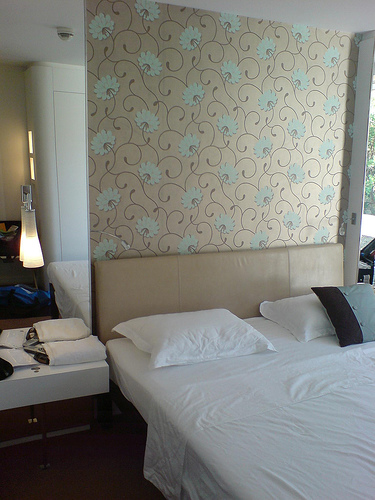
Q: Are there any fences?
A: No, there are no fences.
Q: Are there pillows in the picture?
A: Yes, there is a pillow.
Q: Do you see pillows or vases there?
A: Yes, there is a pillow.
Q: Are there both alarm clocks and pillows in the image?
A: No, there is a pillow but no alarm clocks.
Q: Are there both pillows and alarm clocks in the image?
A: No, there is a pillow but no alarm clocks.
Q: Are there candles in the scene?
A: No, there are no candles.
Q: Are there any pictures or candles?
A: No, there are no candles or pictures.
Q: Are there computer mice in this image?
A: No, there are no computer mice.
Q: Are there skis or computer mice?
A: No, there are no computer mice or skis.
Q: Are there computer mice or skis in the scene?
A: No, there are no computer mice or skis.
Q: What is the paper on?
A: The paper is on the counter.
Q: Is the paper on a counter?
A: Yes, the paper is on a counter.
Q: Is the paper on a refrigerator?
A: No, the paper is on a counter.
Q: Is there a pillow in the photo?
A: Yes, there are pillows.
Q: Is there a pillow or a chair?
A: Yes, there are pillows.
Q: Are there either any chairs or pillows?
A: Yes, there are pillows.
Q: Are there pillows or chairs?
A: Yes, there are pillows.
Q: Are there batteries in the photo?
A: No, there are no batteries.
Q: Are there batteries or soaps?
A: No, there are no batteries or soaps.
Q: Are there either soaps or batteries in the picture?
A: No, there are no batteries or soaps.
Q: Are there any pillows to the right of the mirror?
A: Yes, there are pillows to the right of the mirror.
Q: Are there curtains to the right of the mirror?
A: No, there are pillows to the right of the mirror.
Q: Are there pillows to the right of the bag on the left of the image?
A: Yes, there are pillows to the right of the bag.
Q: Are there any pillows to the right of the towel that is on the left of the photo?
A: Yes, there are pillows to the right of the towel.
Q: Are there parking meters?
A: No, there are no parking meters.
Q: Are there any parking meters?
A: No, there are no parking meters.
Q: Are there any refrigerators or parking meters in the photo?
A: No, there are no parking meters or refrigerators.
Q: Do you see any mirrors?
A: Yes, there is a mirror.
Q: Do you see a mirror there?
A: Yes, there is a mirror.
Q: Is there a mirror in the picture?
A: Yes, there is a mirror.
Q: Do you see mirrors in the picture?
A: Yes, there is a mirror.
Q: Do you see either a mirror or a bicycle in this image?
A: Yes, there is a mirror.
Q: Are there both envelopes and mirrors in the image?
A: No, there is a mirror but no envelopes.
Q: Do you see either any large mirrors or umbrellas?
A: Yes, there is a large mirror.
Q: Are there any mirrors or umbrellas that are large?
A: Yes, the mirror is large.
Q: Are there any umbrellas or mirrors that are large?
A: Yes, the mirror is large.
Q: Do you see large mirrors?
A: Yes, there is a large mirror.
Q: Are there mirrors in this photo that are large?
A: Yes, there is a mirror that is large.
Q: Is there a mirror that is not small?
A: Yes, there is a large mirror.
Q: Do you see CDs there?
A: No, there are no cds.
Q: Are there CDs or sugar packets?
A: No, there are no CDs or sugar packets.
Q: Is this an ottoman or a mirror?
A: This is a mirror.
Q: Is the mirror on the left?
A: Yes, the mirror is on the left of the image.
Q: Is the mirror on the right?
A: No, the mirror is on the left of the image.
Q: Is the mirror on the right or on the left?
A: The mirror is on the left of the image.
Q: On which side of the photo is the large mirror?
A: The mirror is on the left of the image.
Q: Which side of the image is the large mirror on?
A: The mirror is on the left of the image.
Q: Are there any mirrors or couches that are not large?
A: No, there is a mirror but it is large.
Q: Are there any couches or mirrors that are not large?
A: No, there is a mirror but it is large.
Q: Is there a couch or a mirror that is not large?
A: No, there is a mirror but it is large.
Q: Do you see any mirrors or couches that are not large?
A: No, there is a mirror but it is large.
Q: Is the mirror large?
A: Yes, the mirror is large.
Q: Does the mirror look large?
A: Yes, the mirror is large.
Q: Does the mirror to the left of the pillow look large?
A: Yes, the mirror is large.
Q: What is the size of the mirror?
A: The mirror is large.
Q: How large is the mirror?
A: The mirror is large.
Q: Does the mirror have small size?
A: No, the mirror is large.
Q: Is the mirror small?
A: No, the mirror is large.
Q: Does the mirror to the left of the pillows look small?
A: No, the mirror is large.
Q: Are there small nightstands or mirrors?
A: No, there is a mirror but it is large.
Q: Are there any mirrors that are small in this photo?
A: No, there is a mirror but it is large.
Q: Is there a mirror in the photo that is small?
A: No, there is a mirror but it is large.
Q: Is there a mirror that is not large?
A: No, there is a mirror but it is large.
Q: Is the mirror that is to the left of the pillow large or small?
A: The mirror is large.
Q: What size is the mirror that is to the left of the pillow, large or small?
A: The mirror is large.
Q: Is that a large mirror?
A: Yes, that is a large mirror.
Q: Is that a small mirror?
A: No, that is a large mirror.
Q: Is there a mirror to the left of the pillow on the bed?
A: Yes, there is a mirror to the left of the pillow.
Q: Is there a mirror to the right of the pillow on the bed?
A: No, the mirror is to the left of the pillow.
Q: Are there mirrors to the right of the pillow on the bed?
A: No, the mirror is to the left of the pillow.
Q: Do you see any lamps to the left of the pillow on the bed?
A: No, there is a mirror to the left of the pillow.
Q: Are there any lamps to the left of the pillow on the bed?
A: No, there is a mirror to the left of the pillow.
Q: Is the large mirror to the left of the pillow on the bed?
A: Yes, the mirror is to the left of the pillow.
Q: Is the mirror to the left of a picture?
A: No, the mirror is to the left of the pillow.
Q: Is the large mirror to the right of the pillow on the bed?
A: No, the mirror is to the left of the pillow.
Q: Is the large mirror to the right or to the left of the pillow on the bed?
A: The mirror is to the left of the pillow.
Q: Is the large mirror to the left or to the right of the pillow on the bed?
A: The mirror is to the left of the pillow.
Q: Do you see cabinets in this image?
A: Yes, there is a cabinet.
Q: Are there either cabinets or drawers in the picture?
A: Yes, there is a cabinet.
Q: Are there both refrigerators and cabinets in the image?
A: No, there is a cabinet but no refrigerators.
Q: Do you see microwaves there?
A: No, there are no microwaves.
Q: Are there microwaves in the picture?
A: No, there are no microwaves.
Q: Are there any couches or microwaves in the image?
A: No, there are no microwaves or couches.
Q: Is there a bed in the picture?
A: Yes, there is a bed.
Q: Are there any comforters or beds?
A: Yes, there is a bed.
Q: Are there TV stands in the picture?
A: No, there are no TV stands.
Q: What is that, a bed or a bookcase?
A: That is a bed.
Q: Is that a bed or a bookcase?
A: That is a bed.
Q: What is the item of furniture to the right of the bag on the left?
A: The piece of furniture is a bed.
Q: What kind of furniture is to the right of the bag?
A: The piece of furniture is a bed.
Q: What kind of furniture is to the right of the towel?
A: The piece of furniture is a bed.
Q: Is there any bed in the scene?
A: Yes, there is a bed.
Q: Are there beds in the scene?
A: Yes, there is a bed.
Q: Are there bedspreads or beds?
A: Yes, there is a bed.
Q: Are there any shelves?
A: No, there are no shelves.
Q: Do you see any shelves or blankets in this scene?
A: No, there are no shelves or blankets.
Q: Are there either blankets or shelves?
A: No, there are no shelves or blankets.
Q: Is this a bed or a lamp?
A: This is a bed.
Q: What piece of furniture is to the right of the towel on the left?
A: The piece of furniture is a bed.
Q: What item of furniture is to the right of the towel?
A: The piece of furniture is a bed.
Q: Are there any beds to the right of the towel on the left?
A: Yes, there is a bed to the right of the towel.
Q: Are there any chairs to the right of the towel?
A: No, there is a bed to the right of the towel.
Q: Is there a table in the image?
A: Yes, there is a table.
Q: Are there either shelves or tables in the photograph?
A: Yes, there is a table.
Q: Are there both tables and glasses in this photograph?
A: No, there is a table but no glasses.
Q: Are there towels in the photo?
A: Yes, there is a towel.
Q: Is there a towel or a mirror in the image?
A: Yes, there is a towel.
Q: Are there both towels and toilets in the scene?
A: No, there is a towel but no toilets.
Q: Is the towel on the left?
A: Yes, the towel is on the left of the image.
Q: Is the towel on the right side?
A: No, the towel is on the left of the image.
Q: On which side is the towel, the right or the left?
A: The towel is on the left of the image.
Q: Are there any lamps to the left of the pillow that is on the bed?
A: No, there is a towel to the left of the pillow.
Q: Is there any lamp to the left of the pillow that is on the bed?
A: No, there is a towel to the left of the pillow.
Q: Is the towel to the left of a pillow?
A: Yes, the towel is to the left of a pillow.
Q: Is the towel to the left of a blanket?
A: No, the towel is to the left of a pillow.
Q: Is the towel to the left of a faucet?
A: No, the towel is to the left of a bed.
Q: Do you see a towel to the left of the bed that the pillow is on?
A: Yes, there is a towel to the left of the bed.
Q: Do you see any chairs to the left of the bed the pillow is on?
A: No, there is a towel to the left of the bed.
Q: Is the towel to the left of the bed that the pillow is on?
A: Yes, the towel is to the left of the bed.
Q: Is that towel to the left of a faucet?
A: No, the towel is to the left of the bed.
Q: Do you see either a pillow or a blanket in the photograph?
A: Yes, there is a pillow.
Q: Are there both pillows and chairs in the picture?
A: No, there is a pillow but no chairs.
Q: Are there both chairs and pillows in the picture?
A: No, there is a pillow but no chairs.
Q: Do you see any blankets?
A: No, there are no blankets.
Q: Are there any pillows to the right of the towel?
A: Yes, there is a pillow to the right of the towel.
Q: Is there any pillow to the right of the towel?
A: Yes, there is a pillow to the right of the towel.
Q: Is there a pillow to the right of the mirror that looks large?
A: Yes, there is a pillow to the right of the mirror.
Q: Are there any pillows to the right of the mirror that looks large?
A: Yes, there is a pillow to the right of the mirror.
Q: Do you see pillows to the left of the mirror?
A: No, the pillow is to the right of the mirror.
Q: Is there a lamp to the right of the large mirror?
A: No, there is a pillow to the right of the mirror.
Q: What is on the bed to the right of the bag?
A: The pillow is on the bed.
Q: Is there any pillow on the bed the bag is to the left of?
A: Yes, there is a pillow on the bed.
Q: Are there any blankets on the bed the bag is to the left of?
A: No, there is a pillow on the bed.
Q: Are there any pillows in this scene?
A: Yes, there is a pillow.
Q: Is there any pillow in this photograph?
A: Yes, there is a pillow.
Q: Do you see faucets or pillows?
A: Yes, there is a pillow.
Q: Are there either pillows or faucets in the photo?
A: Yes, there is a pillow.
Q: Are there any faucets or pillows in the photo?
A: Yes, there is a pillow.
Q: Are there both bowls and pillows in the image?
A: No, there is a pillow but no bowls.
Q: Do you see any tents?
A: No, there are no tents.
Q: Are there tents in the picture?
A: No, there are no tents.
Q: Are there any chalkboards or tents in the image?
A: No, there are no tents or chalkboards.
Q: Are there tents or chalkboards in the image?
A: No, there are no tents or chalkboards.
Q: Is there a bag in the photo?
A: Yes, there is a bag.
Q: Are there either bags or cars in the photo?
A: Yes, there is a bag.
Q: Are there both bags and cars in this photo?
A: No, there is a bag but no cars.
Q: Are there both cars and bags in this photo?
A: No, there is a bag but no cars.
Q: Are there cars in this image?
A: No, there are no cars.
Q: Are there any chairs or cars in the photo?
A: No, there are no cars or chairs.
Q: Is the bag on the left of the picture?
A: Yes, the bag is on the left of the image.